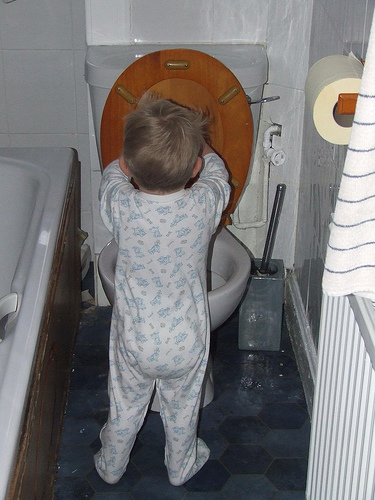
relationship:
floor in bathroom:
[50, 259, 312, 498] [1, 0, 374, 497]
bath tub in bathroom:
[0, 147, 87, 497] [1, 0, 374, 497]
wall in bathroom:
[293, 1, 374, 353] [1, 0, 374, 497]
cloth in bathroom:
[322, 7, 375, 302] [1, 0, 374, 497]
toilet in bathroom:
[84, 42, 280, 413] [1, 0, 374, 497]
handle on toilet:
[244, 94, 280, 107] [84, 42, 280, 413]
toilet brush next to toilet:
[254, 185, 285, 277] [84, 42, 280, 413]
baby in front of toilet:
[94, 99, 231, 488] [84, 42, 280, 413]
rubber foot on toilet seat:
[164, 60, 191, 71] [100, 47, 252, 226]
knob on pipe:
[270, 149, 286, 166] [233, 124, 286, 230]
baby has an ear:
[94, 99, 231, 488] [191, 157, 203, 182]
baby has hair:
[94, 99, 231, 488] [121, 90, 212, 195]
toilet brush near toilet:
[254, 185, 285, 277] [84, 42, 280, 413]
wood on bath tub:
[2, 159, 82, 499] [0, 147, 87, 497]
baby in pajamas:
[94, 99, 231, 488] [93, 153, 232, 487]